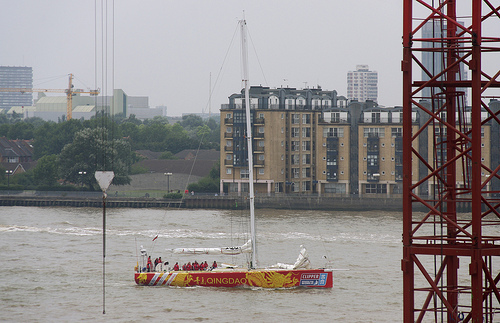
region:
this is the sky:
[130, 3, 193, 82]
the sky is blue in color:
[138, 35, 185, 72]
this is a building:
[283, 80, 361, 182]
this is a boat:
[148, 265, 328, 285]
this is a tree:
[46, 130, 83, 175]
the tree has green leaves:
[36, 158, 63, 187]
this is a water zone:
[11, 242, 73, 302]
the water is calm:
[14, 243, 54, 295]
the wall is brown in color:
[266, 112, 279, 190]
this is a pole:
[243, 55, 257, 207]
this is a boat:
[250, 262, 322, 288]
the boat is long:
[235, 265, 327, 284]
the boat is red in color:
[279, 266, 326, 286]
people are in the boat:
[145, 254, 220, 274]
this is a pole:
[237, 152, 268, 208]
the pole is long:
[240, 153, 264, 195]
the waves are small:
[17, 217, 89, 254]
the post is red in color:
[407, 74, 484, 221]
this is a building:
[305, 114, 370, 171]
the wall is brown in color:
[265, 115, 281, 148]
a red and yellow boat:
[121, 10, 349, 303]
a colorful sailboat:
[126, 6, 352, 303]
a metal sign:
[83, 157, 119, 199]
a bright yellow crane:
[0, 66, 113, 140]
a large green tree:
[45, 121, 137, 209]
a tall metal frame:
[396, 1, 486, 313]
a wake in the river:
[55, 215, 210, 243]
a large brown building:
[205, 72, 485, 207]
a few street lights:
[73, 165, 90, 180]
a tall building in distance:
[336, 56, 388, 116]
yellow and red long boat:
[121, 246, 331, 303]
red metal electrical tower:
[405, 0, 493, 310]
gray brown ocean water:
[46, 225, 88, 305]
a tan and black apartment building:
[215, 80, 430, 193]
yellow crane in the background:
[16, 74, 130, 143]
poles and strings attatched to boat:
[201, 24, 315, 234]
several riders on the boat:
[138, 253, 227, 274]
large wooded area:
[32, 105, 210, 185]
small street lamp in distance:
[158, 168, 182, 181]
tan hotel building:
[344, 50, 383, 113]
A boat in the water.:
[120, 225, 371, 305]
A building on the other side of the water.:
[210, 50, 495, 195]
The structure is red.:
[390, 5, 495, 320]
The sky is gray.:
[121, 7, 178, 62]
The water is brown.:
[13, 215, 88, 320]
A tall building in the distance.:
[0, 61, 40, 112]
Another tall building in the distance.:
[340, 55, 381, 101]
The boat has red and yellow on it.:
[116, 260, 351, 295]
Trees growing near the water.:
[40, 118, 131, 168]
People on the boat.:
[140, 251, 229, 270]